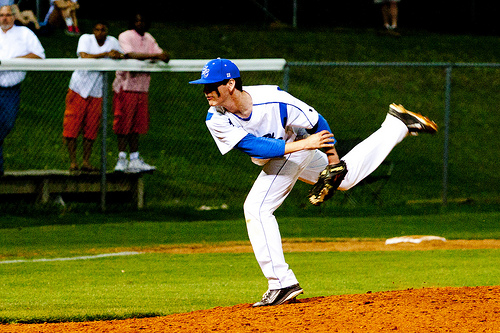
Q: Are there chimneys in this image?
A: No, there are no chimneys.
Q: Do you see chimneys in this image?
A: No, there are no chimneys.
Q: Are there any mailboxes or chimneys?
A: No, there are no chimneys or mailboxes.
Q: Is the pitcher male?
A: Yes, the pitcher is male.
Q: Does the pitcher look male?
A: Yes, the pitcher is male.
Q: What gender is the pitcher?
A: The pitcher is male.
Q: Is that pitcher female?
A: No, the pitcher is male.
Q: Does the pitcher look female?
A: No, the pitcher is male.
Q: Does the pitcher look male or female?
A: The pitcher is male.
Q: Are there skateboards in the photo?
A: No, there are no skateboards.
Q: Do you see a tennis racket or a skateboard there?
A: No, there are no skateboards or rackets.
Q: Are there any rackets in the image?
A: No, there are no rackets.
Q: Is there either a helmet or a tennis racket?
A: No, there are no rackets or helmets.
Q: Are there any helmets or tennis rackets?
A: No, there are no tennis rackets or helmets.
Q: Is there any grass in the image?
A: Yes, there is grass.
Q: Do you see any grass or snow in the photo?
A: Yes, there is grass.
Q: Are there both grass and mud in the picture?
A: No, there is grass but no mud.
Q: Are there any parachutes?
A: No, there are no parachutes.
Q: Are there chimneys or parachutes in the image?
A: No, there are no parachutes or chimneys.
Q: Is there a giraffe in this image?
A: No, there are no giraffes.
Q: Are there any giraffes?
A: No, there are no giraffes.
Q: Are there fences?
A: Yes, there is a fence.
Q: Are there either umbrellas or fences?
A: Yes, there is a fence.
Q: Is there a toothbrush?
A: No, there are no toothbrushes.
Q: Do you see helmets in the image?
A: No, there are no helmets.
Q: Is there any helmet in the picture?
A: No, there are no helmets.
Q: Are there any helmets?
A: No, there are no helmets.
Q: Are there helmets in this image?
A: No, there are no helmets.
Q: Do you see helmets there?
A: No, there are no helmets.